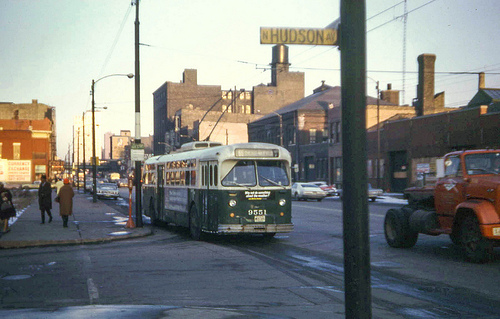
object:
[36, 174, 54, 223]
people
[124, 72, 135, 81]
light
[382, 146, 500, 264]
vehicle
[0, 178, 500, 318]
road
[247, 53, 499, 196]
building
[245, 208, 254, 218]
number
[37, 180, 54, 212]
coat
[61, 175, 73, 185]
hat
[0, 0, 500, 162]
sky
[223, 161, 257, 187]
windshield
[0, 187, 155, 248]
sidewalk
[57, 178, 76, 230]
person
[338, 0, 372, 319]
pole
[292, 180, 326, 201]
cars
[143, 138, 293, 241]
bus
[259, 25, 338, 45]
sign